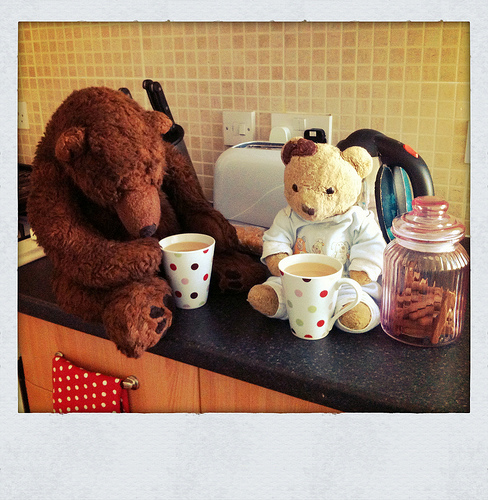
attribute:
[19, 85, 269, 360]
bear — brown, big, furry, stuffed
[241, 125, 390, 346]
bear — beige, small, furry, stuffed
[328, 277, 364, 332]
handle — white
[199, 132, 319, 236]
toaster — white